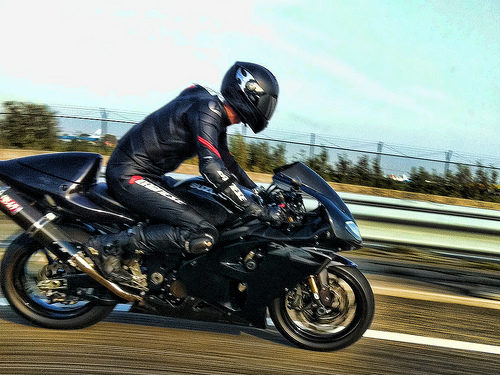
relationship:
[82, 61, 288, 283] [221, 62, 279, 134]
cyclist wearing helmet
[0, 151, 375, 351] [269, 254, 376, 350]
motorcycle has front tire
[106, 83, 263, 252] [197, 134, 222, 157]
black suit has red stripe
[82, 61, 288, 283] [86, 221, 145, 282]
cyclist has boot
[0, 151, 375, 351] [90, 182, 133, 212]
motorcycle has black seat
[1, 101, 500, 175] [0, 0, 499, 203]
bridge in background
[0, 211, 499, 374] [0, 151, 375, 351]
road under motorcycle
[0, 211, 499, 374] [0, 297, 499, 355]
street has a white stripe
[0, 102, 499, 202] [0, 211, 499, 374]
plants are beside road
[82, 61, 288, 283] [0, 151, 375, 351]
man riding motorcycle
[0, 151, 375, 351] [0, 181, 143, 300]
motorcycle has exhaust pipe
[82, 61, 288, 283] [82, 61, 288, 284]
cyclist in person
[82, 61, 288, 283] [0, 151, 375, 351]
person on top of motorcycle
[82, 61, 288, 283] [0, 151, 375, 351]
person on motorcycle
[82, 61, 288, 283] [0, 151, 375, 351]
person riding on motorcycle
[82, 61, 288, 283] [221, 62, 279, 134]
man wearing helmet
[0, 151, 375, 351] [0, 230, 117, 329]
motorcycle has rear tire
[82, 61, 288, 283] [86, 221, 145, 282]
cyclist has a right boot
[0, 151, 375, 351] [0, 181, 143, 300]
motorcycle has tailpipe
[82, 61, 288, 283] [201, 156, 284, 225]
cyclist has right glove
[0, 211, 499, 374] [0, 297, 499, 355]
road has white stripe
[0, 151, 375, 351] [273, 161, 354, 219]
motorcycle has windshield